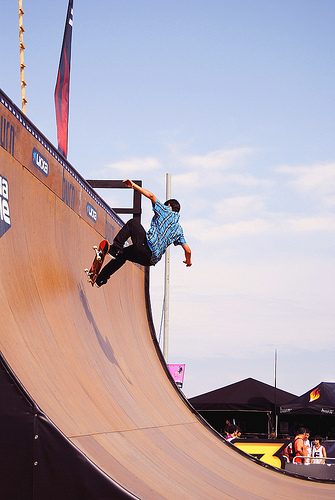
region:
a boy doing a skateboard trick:
[82, 176, 195, 290]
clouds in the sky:
[218, 150, 284, 236]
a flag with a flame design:
[50, 0, 81, 157]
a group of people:
[290, 428, 328, 463]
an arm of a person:
[122, 175, 160, 203]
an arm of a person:
[179, 235, 196, 269]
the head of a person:
[162, 194, 185, 213]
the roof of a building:
[188, 372, 292, 404]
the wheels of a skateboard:
[90, 243, 102, 261]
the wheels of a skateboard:
[83, 266, 94, 286]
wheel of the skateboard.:
[91, 253, 102, 259]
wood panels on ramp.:
[83, 388, 114, 410]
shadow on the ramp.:
[101, 336, 117, 366]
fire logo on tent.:
[305, 385, 322, 404]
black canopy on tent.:
[224, 382, 252, 397]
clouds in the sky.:
[216, 207, 260, 235]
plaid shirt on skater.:
[158, 219, 171, 236]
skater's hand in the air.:
[179, 260, 196, 268]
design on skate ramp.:
[30, 157, 52, 169]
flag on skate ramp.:
[50, 35, 78, 130]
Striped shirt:
[145, 185, 196, 268]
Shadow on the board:
[61, 272, 155, 391]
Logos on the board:
[3, 112, 130, 231]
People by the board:
[285, 425, 328, 473]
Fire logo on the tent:
[301, 377, 331, 410]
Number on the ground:
[226, 432, 298, 476]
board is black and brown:
[3, 82, 314, 489]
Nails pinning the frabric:
[14, 401, 56, 491]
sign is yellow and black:
[226, 432, 300, 467]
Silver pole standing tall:
[157, 161, 190, 377]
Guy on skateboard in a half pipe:
[80, 171, 197, 294]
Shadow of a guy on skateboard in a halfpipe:
[68, 281, 143, 388]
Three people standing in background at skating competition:
[280, 424, 329, 464]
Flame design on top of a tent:
[301, 384, 324, 407]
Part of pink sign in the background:
[167, 363, 184, 383]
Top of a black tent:
[183, 372, 298, 407]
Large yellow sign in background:
[230, 438, 290, 468]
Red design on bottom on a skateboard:
[78, 234, 113, 292]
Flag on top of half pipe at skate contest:
[50, 0, 82, 156]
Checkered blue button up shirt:
[143, 193, 190, 263]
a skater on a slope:
[78, 170, 202, 295]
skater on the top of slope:
[82, 168, 199, 291]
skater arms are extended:
[78, 165, 196, 293]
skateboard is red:
[78, 228, 114, 291]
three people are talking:
[275, 421, 330, 465]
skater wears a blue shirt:
[94, 172, 198, 284]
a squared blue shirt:
[145, 196, 187, 258]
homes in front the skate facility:
[188, 368, 333, 434]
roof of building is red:
[201, 366, 295, 408]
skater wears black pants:
[92, 170, 196, 298]